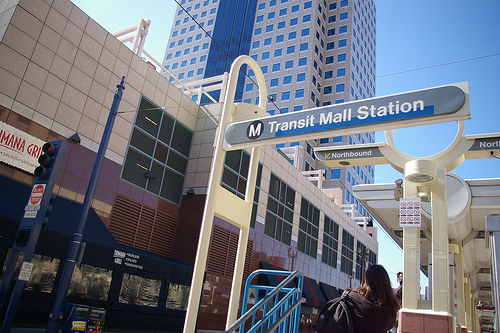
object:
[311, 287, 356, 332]
backpack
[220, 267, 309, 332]
rail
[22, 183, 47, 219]
sign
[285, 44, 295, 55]
windows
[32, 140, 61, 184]
light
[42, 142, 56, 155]
stop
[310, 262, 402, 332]
woman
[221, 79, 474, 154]
sign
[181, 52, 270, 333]
pole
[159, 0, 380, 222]
building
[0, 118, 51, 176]
sign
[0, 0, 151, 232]
wall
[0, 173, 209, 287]
awning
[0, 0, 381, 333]
building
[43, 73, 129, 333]
pole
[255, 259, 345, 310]
awning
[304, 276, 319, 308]
stripes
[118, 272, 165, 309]
window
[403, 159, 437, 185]
fixture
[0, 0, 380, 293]
tiled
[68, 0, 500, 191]
sky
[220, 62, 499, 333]
subway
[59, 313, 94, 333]
boxes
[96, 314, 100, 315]
newspapers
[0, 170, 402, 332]
traffic